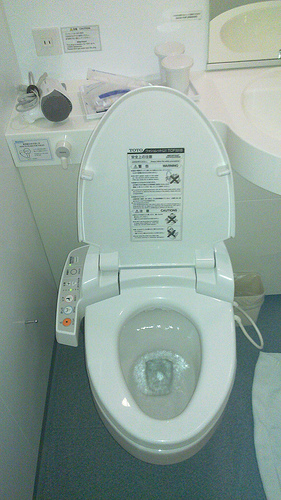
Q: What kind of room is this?
A: Bathroom.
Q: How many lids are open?
A: One.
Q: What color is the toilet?
A: White.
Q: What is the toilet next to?
A: Sink.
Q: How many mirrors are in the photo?
A: One.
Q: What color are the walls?
A: White.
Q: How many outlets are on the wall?
A: One.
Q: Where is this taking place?
A: In a very small modern bathroom.